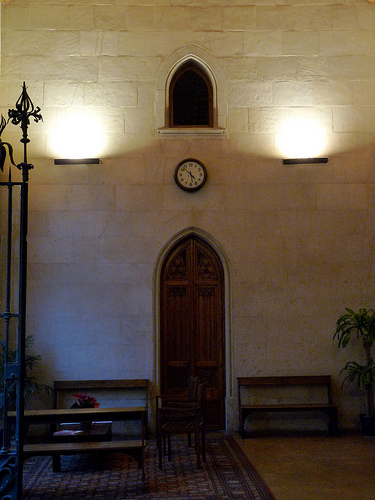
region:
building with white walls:
[1, 6, 373, 435]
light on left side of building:
[38, 95, 117, 167]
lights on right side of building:
[271, 102, 334, 165]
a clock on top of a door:
[171, 154, 207, 193]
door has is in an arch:
[146, 218, 242, 441]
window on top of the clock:
[152, 45, 232, 136]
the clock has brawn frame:
[165, 154, 212, 197]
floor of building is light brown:
[244, 424, 373, 496]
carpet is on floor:
[10, 432, 276, 498]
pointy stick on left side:
[4, 76, 45, 376]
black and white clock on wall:
[170, 148, 217, 194]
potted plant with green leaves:
[336, 307, 373, 441]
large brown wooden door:
[150, 227, 233, 401]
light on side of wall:
[41, 102, 121, 174]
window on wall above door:
[129, 43, 253, 139]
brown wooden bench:
[231, 370, 342, 438]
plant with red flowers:
[64, 391, 105, 409]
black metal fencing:
[0, 165, 40, 362]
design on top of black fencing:
[9, 83, 45, 146]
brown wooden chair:
[151, 377, 213, 468]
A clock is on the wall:
[171, 148, 212, 199]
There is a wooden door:
[151, 221, 238, 435]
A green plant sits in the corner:
[332, 295, 373, 443]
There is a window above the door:
[152, 39, 232, 154]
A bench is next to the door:
[234, 367, 341, 435]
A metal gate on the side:
[2, 126, 25, 496]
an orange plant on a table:
[62, 385, 108, 437]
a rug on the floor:
[0, 423, 276, 498]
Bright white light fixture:
[255, 101, 352, 176]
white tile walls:
[45, 225, 122, 330]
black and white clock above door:
[171, 156, 216, 197]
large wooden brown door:
[152, 229, 228, 381]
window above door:
[150, 44, 235, 143]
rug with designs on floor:
[95, 465, 258, 498]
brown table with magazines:
[50, 419, 118, 466]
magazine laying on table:
[52, 426, 87, 439]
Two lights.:
[45, 105, 334, 167]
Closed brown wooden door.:
[151, 224, 235, 436]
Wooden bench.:
[237, 371, 343, 438]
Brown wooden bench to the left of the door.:
[49, 375, 151, 443]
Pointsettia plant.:
[67, 389, 100, 430]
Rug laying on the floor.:
[4, 433, 276, 498]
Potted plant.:
[333, 303, 374, 433]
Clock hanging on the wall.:
[171, 152, 207, 191]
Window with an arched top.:
[159, 52, 227, 136]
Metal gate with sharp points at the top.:
[1, 78, 46, 498]